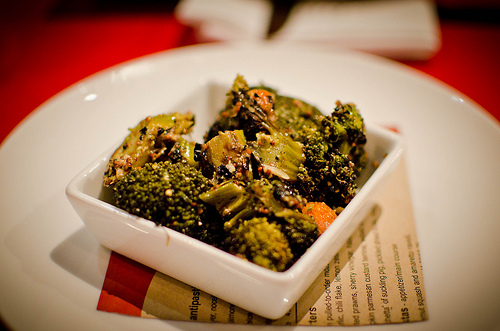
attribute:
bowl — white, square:
[57, 71, 412, 324]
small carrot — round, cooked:
[298, 200, 336, 225]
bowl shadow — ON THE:
[52, 204, 388, 327]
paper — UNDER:
[90, 113, 429, 324]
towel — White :
[172, 1, 438, 61]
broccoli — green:
[106, 76, 365, 269]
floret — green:
[109, 159, 216, 234]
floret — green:
[301, 100, 368, 199]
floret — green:
[221, 218, 296, 269]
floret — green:
[269, 209, 317, 247]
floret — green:
[229, 87, 274, 136]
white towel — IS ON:
[144, 4, 458, 74]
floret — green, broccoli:
[168, 111, 395, 202]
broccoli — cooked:
[177, 106, 334, 228]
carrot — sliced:
[300, 197, 337, 234]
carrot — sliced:
[224, 86, 276, 116]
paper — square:
[96, 125, 436, 329]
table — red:
[1, 14, 498, 144]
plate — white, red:
[37, 81, 476, 328]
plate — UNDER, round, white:
[0, 45, 485, 328]